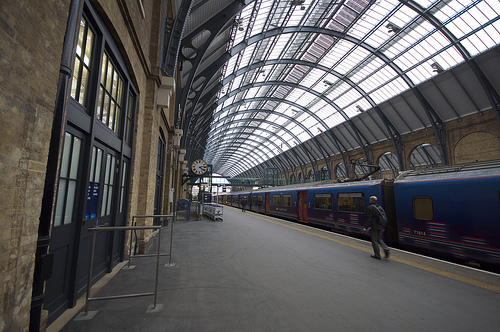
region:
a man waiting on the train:
[237, 187, 249, 217]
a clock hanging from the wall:
[190, 156, 213, 179]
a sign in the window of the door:
[82, 171, 107, 225]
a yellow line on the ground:
[299, 219, 321, 251]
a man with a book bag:
[366, 192, 391, 236]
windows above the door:
[94, 42, 130, 135]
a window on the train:
[409, 188, 434, 233]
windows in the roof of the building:
[246, 98, 288, 148]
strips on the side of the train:
[428, 213, 450, 246]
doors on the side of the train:
[293, 184, 312, 229]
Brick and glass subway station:
[0, 0, 496, 331]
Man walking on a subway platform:
[362, 192, 391, 262]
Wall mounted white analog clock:
[179, 156, 209, 187]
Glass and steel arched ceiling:
[166, 0, 498, 184]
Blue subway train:
[210, 158, 497, 281]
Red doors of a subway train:
[292, 185, 311, 223]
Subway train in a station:
[205, 158, 499, 280]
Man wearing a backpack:
[360, 193, 391, 261]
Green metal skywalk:
[187, 166, 317, 188]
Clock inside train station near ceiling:
[192, 160, 207, 174]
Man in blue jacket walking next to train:
[361, 193, 393, 258]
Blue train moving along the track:
[203, 158, 498, 279]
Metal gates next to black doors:
[83, 213, 175, 329]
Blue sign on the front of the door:
[83, 180, 102, 221]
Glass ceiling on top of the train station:
[197, 2, 495, 187]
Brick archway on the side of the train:
[450, 128, 497, 163]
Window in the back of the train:
[409, 193, 434, 220]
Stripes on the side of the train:
[398, 223, 499, 267]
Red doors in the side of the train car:
[296, 190, 308, 221]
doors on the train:
[294, 182, 311, 226]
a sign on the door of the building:
[84, 177, 103, 226]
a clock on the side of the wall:
[185, 154, 211, 181]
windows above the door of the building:
[93, 47, 132, 135]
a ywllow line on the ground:
[415, 250, 445, 290]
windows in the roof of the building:
[246, 88, 288, 153]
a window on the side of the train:
[410, 193, 444, 228]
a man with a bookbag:
[369, 195, 392, 232]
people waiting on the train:
[235, 189, 252, 215]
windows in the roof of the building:
[270, 41, 336, 126]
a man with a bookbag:
[358, 187, 388, 237]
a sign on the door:
[85, 177, 108, 230]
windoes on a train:
[331, 179, 362, 212]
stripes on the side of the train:
[427, 214, 447, 239]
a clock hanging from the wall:
[182, 155, 216, 185]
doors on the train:
[291, 187, 311, 223]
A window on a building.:
[403, 142, 445, 160]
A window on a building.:
[352, 161, 371, 173]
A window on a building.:
[333, 162, 350, 176]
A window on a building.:
[354, 155, 366, 172]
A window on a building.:
[319, 163, 329, 173]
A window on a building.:
[308, 167, 317, 178]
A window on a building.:
[299, 170, 304, 179]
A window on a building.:
[289, 172, 296, 179]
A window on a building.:
[56, 130, 81, 223]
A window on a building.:
[67, 12, 96, 109]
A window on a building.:
[322, 166, 332, 181]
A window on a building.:
[306, 169, 316, 181]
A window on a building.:
[298, 172, 307, 184]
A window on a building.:
[288, 174, 302, 185]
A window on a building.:
[89, 140, 104, 221]